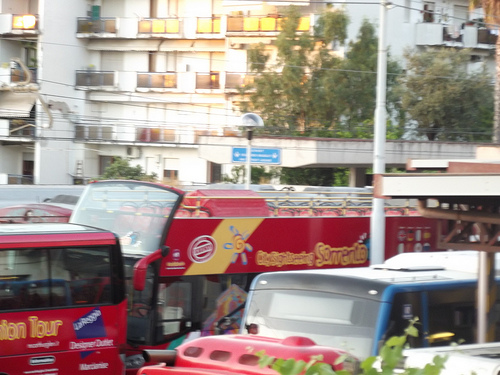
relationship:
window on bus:
[1, 241, 131, 308] [0, 220, 135, 374]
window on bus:
[153, 277, 195, 343] [71, 177, 494, 372]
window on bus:
[65, 182, 182, 257] [71, 177, 494, 372]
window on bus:
[120, 260, 156, 347] [71, 177, 494, 372]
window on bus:
[199, 275, 252, 332] [71, 177, 494, 372]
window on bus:
[253, 279, 395, 356] [239, 249, 500, 375]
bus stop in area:
[370, 145, 495, 360] [367, 153, 497, 370]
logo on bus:
[187, 233, 214, 263] [59, 175, 495, 375]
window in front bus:
[397, 290, 424, 350] [239, 249, 498, 361]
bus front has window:
[239, 249, 498, 361] [397, 290, 424, 350]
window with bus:
[428, 286, 478, 346] [239, 249, 500, 375]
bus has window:
[239, 249, 500, 375] [428, 286, 478, 346]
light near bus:
[236, 112, 266, 127] [71, 177, 494, 372]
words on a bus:
[1, 311, 63, 341] [0, 220, 135, 374]